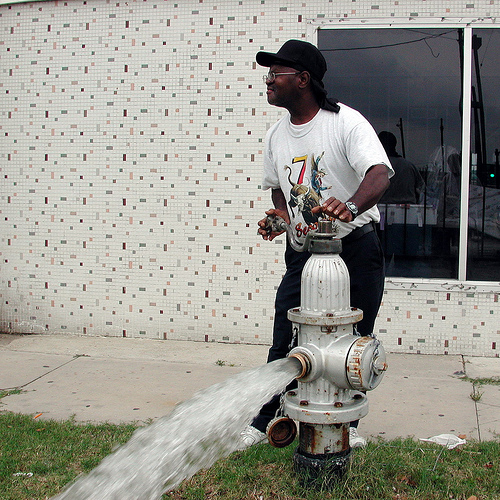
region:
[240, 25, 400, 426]
the man wearing glasses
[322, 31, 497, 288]
window behind the man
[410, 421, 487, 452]
garbage on the ground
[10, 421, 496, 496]
grass beside the hydrant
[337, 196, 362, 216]
the watch on the wrist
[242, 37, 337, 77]
man wearing the hat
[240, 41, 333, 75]
the hat is black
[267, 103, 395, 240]
man wearing the t shirt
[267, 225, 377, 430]
man wearing pants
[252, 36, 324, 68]
black hat on head of man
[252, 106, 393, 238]
white shirt on man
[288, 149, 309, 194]
number on front of shirt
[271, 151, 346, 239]
graphic on front of shirt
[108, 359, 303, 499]
water gushing out of hydrant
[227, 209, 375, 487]
white fire hydrant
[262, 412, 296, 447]
rusty cap on hydrant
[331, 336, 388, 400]
white cap on hydrant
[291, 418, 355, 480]
rusty base of hydrant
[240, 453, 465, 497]
green grass below hydrant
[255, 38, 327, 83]
A black hat on a man's head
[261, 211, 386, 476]
A silver hydrant in the grass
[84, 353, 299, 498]
Powerful stream of water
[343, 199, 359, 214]
A wristwatch on a man's arm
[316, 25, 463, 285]
Reflections in a store window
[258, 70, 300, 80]
Eyeglasses on a man's face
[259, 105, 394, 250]
White shirt on a man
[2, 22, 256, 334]
Small tiles on a store wall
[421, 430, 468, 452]
Litter on the ground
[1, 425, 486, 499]
Green grass around a sidewalk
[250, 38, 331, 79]
a black baseball cap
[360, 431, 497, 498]
a section of green grass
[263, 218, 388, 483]
an old white water fountain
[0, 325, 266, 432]
part of a concrete sidewalk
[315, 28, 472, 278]
a large window of a building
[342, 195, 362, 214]
a man's watch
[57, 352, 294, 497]
a large stream of water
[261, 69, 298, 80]
a man's eyeglasses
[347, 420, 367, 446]
part of a white tennis shoe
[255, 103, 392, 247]
a white shirt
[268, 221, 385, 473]
White fire hydrant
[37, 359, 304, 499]
Water gushing out of the fire hydrant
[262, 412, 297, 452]
Cap for the fire hydrant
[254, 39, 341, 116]
Hat worn by the man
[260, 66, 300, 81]
Pair of glasses worn by the man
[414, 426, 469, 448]
Piece of tissue on the ground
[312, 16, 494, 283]
Row of windows on the house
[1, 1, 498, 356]
House behind the man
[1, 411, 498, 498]
Patch of grass on the floor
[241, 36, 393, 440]
Man activating the fire hydrant